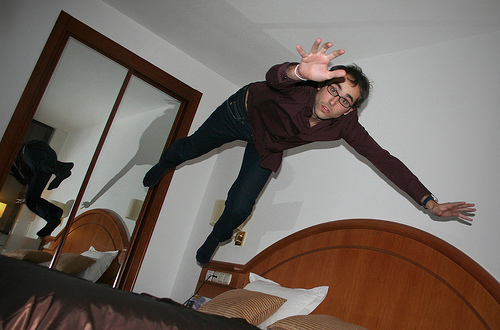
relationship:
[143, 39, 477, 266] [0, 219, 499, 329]
man above bed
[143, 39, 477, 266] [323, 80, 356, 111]
man wearing glasses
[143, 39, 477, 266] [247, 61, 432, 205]
man wearing a shirt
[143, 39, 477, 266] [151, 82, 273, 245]
man wearing jeans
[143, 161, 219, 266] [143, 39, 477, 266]
socks on man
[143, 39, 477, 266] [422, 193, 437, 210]
man wearing a watch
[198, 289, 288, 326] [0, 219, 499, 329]
pillow on bed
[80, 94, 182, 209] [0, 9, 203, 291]
shadow in mirror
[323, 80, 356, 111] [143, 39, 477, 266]
glasses on man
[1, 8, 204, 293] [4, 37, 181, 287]
closet has mirrored doors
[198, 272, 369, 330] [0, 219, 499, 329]
pillows on bed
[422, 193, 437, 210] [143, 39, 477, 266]
watch on man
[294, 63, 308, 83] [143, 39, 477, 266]
bracelet on man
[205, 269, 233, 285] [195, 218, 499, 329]
plugs on headboard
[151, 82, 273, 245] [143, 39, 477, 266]
jeans on man